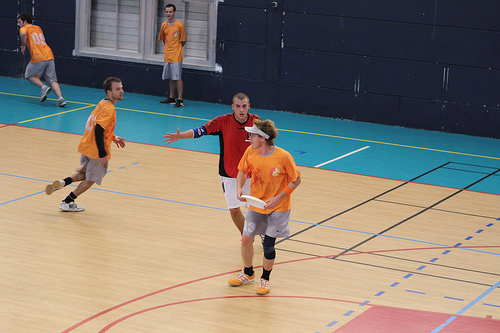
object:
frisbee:
[236, 194, 268, 211]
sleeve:
[92, 123, 109, 158]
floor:
[0, 75, 499, 332]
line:
[429, 281, 498, 332]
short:
[74, 148, 109, 186]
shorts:
[238, 208, 296, 239]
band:
[278, 184, 298, 196]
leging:
[260, 212, 283, 274]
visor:
[239, 126, 259, 137]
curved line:
[99, 295, 375, 333]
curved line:
[61, 245, 498, 332]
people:
[161, 93, 271, 245]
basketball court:
[0, 72, 499, 332]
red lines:
[57, 245, 499, 333]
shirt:
[78, 98, 115, 160]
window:
[88, 2, 120, 49]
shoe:
[58, 199, 87, 215]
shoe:
[42, 179, 65, 197]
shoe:
[256, 275, 271, 295]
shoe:
[226, 271, 255, 288]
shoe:
[38, 85, 50, 105]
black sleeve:
[93, 126, 108, 158]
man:
[42, 75, 127, 213]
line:
[278, 81, 435, 105]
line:
[280, 80, 498, 110]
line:
[279, 47, 440, 66]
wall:
[0, 0, 499, 139]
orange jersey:
[234, 146, 299, 216]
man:
[227, 118, 301, 297]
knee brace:
[263, 235, 276, 261]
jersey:
[187, 113, 262, 178]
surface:
[0, 76, 499, 332]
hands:
[264, 198, 279, 209]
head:
[246, 119, 280, 151]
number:
[245, 222, 258, 234]